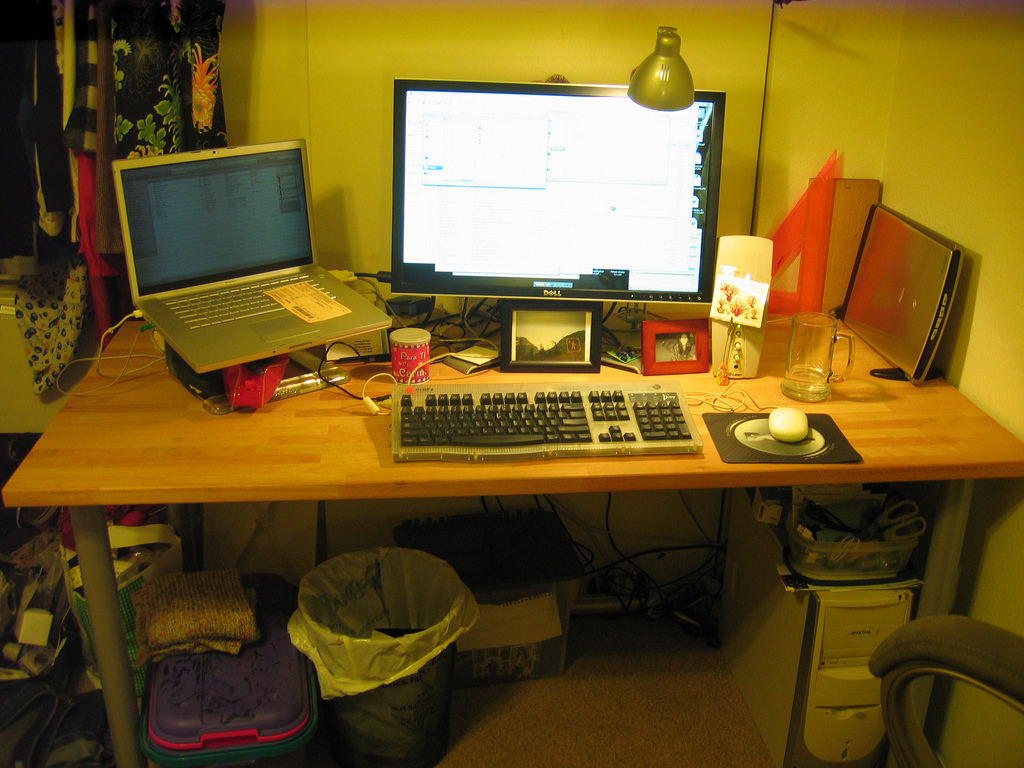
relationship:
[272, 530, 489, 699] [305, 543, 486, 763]
bag in can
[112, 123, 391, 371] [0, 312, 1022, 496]
lap top on desk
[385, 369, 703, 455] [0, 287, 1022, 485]
keyboard on desk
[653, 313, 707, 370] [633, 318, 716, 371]
snap shot on photo frame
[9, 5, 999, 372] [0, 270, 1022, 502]
computers on table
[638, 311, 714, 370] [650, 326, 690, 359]
picture has photo